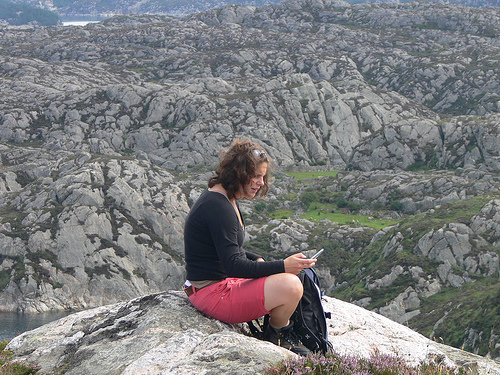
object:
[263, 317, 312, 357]
brown boot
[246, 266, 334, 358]
backpack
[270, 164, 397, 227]
green grass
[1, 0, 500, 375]
mountains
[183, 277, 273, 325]
red shorts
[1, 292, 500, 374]
ground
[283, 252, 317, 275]
hand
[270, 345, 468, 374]
flowers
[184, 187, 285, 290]
shirt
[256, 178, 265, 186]
nose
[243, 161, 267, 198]
woman's face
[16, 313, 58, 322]
water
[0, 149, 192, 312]
hillside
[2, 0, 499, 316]
rocks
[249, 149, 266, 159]
glasses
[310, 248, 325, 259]
cell phone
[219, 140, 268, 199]
head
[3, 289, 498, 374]
rock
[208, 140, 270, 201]
hair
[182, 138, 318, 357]
woman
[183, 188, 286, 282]
black shirt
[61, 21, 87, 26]
water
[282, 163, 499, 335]
foliage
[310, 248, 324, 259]
device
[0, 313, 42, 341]
lake